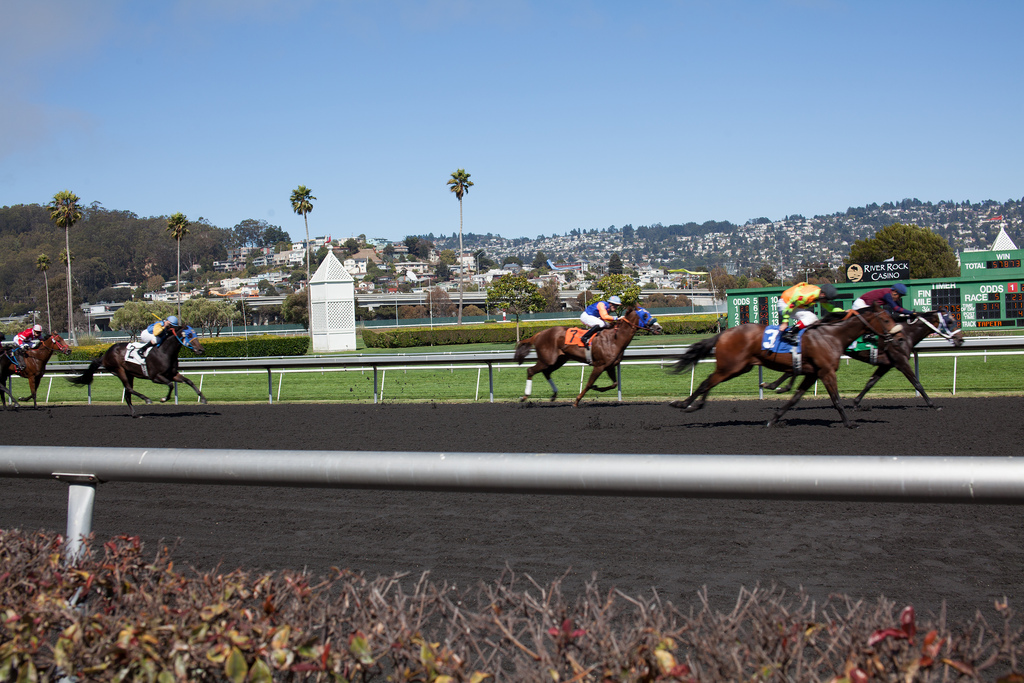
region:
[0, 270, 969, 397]
Horses with jockeys racing.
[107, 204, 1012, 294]
Hill with many houses.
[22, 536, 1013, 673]
Brown leaves and grass.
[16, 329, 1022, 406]
Silver color guardrail near horses.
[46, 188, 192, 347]
Tall skinny branch free trees.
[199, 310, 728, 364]
Row of green hedges.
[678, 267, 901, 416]
Horse with a blue number 3.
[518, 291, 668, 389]
Jockey on the horse number 7.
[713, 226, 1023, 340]
Green and white jockey club house.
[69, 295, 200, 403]
Jockey riding horse number 2.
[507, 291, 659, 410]
brown horse with number 7 on it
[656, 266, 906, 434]
horse with number 3 in blue on it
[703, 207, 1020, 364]
building color is green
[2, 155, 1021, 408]
palm trees behind the grass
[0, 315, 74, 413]
man on horse wearing red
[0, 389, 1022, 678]
road with black concrete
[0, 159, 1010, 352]
hill behind palm trees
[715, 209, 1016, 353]
rock casino behind horse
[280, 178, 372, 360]
white tower house in front of palm tree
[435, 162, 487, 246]
palm tree in the distance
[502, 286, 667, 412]
jockey on a horse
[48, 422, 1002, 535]
metal bar of a fence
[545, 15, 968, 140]
blue sky in the distance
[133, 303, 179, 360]
jockey riding a dark brown horse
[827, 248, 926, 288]
sign on a building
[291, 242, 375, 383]
building at a horse track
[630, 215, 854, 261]
buildings on a hill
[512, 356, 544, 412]
back leg of a horse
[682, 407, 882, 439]
shadow casted on the ground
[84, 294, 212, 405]
brown horse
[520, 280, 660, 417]
brown horse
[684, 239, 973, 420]
horses running in race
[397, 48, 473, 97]
white clouds in blue sky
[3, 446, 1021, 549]
A silver rail is on a vertical post.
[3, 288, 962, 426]
Five horses are racing each other.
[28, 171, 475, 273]
Palm trees have green tops.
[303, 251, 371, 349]
A white building has a pointed top.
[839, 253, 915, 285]
A sign advertises a casino in white letters.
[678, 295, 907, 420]
A horse has a white three on the side.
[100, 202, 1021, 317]
A town is on the hill behind the racetrack.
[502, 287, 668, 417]
A horse with a 7 tagged on it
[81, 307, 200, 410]
A horse with a tagged 2 on it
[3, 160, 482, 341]
A row of palm trees in the distance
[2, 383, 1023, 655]
The track the horses are running on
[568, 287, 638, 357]
A jokey riding a horse labeled 7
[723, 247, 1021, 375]
The scoreboard for the horse races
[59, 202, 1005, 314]
The city the horse race is being held in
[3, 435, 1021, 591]
The bar that denotes were the track is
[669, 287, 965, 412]
two horses vying for the lead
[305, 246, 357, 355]
a building that is closed up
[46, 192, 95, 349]
a palm tree near the track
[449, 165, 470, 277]
a palm tree on the side of the hill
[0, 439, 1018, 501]
a rail on the side of the track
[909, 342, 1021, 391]
the inside rail of the track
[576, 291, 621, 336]
jockey dressed in blue and white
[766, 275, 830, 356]
a jockey standing in the saddle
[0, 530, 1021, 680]
a row of bushes with no leaves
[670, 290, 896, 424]
second horse is 3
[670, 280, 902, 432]
second horse is brown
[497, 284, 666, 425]
third horse is 7